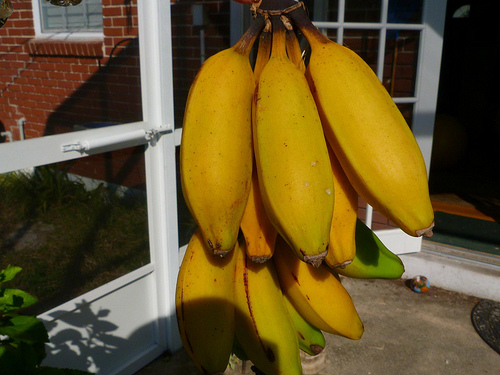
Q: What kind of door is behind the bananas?
A: French.